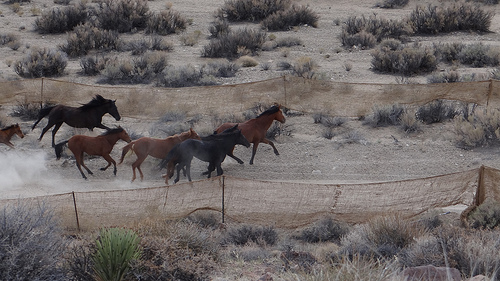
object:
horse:
[0, 123, 24, 151]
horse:
[32, 93, 122, 148]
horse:
[55, 124, 132, 181]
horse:
[117, 128, 203, 186]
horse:
[156, 129, 251, 185]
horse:
[213, 105, 286, 165]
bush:
[13, 44, 68, 79]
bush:
[35, 4, 82, 30]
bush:
[63, 26, 132, 51]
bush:
[105, 51, 158, 79]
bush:
[200, 27, 264, 57]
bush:
[267, 2, 315, 31]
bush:
[335, 7, 406, 47]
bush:
[366, 39, 445, 73]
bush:
[68, 230, 162, 281]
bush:
[148, 225, 205, 261]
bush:
[239, 217, 278, 245]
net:
[157, 87, 193, 96]